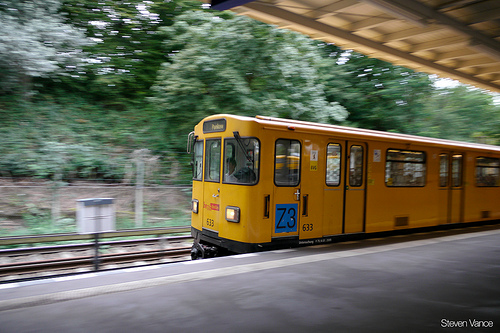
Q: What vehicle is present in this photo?
A: Train.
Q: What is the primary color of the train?
A: Yellow.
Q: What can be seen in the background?
A: Trees.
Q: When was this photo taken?
A: In the daytime.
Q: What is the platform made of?
A: Concrete.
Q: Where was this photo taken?
A: At the train station.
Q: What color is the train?
A: Yellow.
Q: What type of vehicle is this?
A: A train.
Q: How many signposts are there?
A: One.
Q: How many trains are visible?
A: One.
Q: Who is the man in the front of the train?
A: The operator.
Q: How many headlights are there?
A: Two.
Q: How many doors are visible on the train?
A: Six.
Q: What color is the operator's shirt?
A: White.